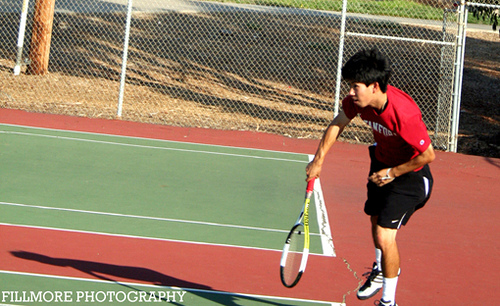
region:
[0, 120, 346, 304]
Green tennis court with white lines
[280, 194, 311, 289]
White, yellow and black tennis racquet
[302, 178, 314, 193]
Red handle of a tennis racquet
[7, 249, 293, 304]
Shadow of a man on a tennis court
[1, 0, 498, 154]
Chain link fence around a tennis court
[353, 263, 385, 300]
White and black tennis shoe with stripes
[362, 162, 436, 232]
Black athletic shorts with a Nike logo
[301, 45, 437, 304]
Man playing tennis on a court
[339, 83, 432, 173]
Red t shirt with white letters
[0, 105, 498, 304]
Red colored area of a tennis court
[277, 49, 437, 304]
a person playing tennis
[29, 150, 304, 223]
a green and white tennis court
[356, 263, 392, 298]
a black and white tennis shoe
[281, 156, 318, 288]
a black and yellow racket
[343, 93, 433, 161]
a red t shirt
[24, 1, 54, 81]
a wooden electric pole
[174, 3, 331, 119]
a chain link fence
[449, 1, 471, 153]
a gray metal pole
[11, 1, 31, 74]
a white metal pole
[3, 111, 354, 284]
red around the tennis court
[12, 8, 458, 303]
a kid is playing tennis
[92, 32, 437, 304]
he is ready for action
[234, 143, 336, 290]
he is holding his racquet downward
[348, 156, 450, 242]
he has on black shorts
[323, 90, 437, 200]
he is wearing a red shirt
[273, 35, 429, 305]
he is jumping off of the ground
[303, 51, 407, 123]
he has a look of anticipation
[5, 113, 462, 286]
the tennis court is red and green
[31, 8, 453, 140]
this tennis court is gated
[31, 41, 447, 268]
the sun is shining on the court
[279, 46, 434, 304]
the boy playing tennis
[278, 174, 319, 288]
the tennis racquet in the boy's hand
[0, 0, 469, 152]
the chain link fence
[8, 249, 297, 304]
the shadow on the ground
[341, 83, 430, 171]
the short sleeved shirt on the boy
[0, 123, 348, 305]
the white lines on the ground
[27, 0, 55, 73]
the wooden pole on the other side of the fence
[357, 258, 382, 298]
the shoe on the boy's foot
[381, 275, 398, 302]
the sock on the boy's leg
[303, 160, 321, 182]
the hand holding the tennis racquet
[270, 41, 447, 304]
person holding tennis racket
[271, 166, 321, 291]
black, white, and yellow tennis racket with red handle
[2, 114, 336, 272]
green and white square patch on tennis court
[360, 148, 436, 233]
black and white athletic shorts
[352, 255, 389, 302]
black and white sneaker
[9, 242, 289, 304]
shadow of tennis player on tennis court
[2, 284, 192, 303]
name of photographer in white lettering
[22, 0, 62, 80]
brown tree trunk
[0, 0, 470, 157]
tall chain link metal fence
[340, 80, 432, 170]
red short sleeve cotton t-shirt